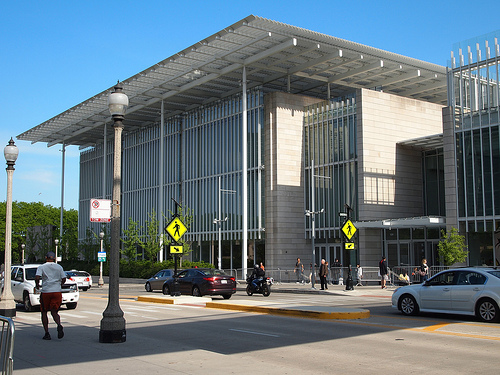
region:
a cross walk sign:
[333, 222, 372, 244]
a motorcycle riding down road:
[245, 272, 270, 294]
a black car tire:
[389, 288, 416, 315]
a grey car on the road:
[407, 283, 451, 318]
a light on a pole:
[87, 93, 134, 122]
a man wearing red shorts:
[38, 298, 63, 313]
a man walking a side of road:
[42, 330, 84, 338]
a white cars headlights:
[66, 284, 83, 301]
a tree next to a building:
[441, 228, 465, 262]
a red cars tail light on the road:
[198, 275, 224, 288]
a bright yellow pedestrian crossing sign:
[163, 217, 190, 242]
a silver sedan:
[391, 265, 498, 316]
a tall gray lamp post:
[98, 79, 138, 339]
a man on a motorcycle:
[245, 265, 273, 298]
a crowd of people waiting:
[286, 257, 431, 285]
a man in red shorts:
[40, 251, 64, 338]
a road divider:
[138, 291, 369, 322]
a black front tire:
[397, 294, 416, 316]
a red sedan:
[160, 268, 235, 300]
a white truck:
[3, 265, 79, 312]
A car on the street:
[391, 268, 498, 320]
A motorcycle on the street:
[247, 263, 269, 295]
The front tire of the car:
[398, 294, 415, 314]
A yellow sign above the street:
[164, 217, 188, 254]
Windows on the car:
[427, 270, 484, 285]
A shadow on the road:
[6, 301, 437, 371]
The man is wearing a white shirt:
[33, 261, 65, 291]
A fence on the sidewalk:
[223, 266, 441, 283]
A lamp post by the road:
[0, 137, 18, 314]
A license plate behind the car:
[218, 278, 228, 283]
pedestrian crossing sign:
[160, 220, 189, 256]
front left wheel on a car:
[397, 293, 417, 318]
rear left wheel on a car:
[472, 296, 497, 322]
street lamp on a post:
[101, 89, 138, 343]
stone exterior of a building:
[276, 129, 300, 232]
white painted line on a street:
[224, 319, 281, 344]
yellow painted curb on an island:
[256, 303, 321, 320]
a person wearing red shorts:
[42, 291, 62, 310]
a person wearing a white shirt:
[33, 261, 66, 292]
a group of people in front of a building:
[261, 242, 394, 289]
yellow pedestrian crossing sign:
[160, 218, 192, 258]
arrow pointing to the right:
[168, 243, 184, 256]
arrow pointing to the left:
[338, 241, 358, 253]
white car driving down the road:
[390, 262, 497, 322]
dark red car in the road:
[156, 265, 241, 300]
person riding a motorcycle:
[234, 261, 278, 296]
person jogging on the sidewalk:
[24, 249, 76, 340]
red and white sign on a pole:
[86, 192, 113, 227]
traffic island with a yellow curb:
[136, 287, 369, 332]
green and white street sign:
[94, 245, 109, 263]